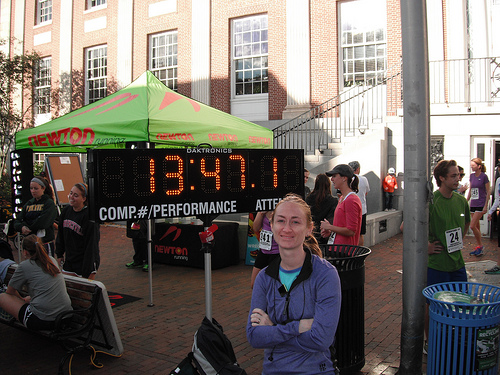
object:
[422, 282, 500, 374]
trash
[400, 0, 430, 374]
pole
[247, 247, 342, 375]
sweater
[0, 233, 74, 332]
lady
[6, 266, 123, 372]
bench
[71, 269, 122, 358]
table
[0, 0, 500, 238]
building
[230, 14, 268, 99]
window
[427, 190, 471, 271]
shirt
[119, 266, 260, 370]
sidewalk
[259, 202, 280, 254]
shirt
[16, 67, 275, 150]
umbrella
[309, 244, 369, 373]
trashbiln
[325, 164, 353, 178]
cap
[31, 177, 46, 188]
headband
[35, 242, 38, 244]
hairtie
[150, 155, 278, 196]
time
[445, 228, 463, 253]
tag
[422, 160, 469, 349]
man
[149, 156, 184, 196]
digits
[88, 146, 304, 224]
clock